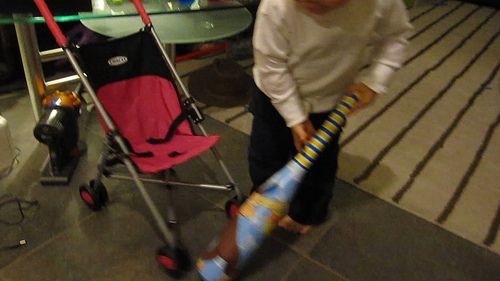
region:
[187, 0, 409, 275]
A child is holding a bat.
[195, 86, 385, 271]
The bat has cartoon characters on it.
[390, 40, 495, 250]
A striped rug.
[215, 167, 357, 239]
The child is barefoot.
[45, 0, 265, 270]
An unoccupied stroller.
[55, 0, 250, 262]
The stroller is red and black.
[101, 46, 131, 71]
The logo of the stroller manufacturer.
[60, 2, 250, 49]
A frosted glass table.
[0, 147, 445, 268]
Tile flooring.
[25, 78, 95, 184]
A handheld vacuum cleaner.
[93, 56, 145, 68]
Label on black portion of stroller.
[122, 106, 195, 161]
Safety belts on stroller.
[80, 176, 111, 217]
Back wheel on stroller.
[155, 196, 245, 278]
Front wheels of stroller.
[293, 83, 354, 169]
Stripes on bat held by child.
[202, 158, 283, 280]
Top of bat held by child standing up.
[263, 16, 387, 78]
White shirt worn by child holding the bat.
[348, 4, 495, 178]
Striped rug behind child holding the bat.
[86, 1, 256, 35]
Round table behind pink and black stroller.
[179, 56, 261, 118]
Brown hat placed on striped rug behind child holding bat.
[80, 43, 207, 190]
Stroller is red and black in color.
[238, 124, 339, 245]
The base ball bat is blue in color.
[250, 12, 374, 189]
Boy is holding the bat.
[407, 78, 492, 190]
The mat is brown in color.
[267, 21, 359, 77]
The boy is white in color.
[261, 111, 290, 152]
pant is black color.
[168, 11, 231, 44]
Table is green in color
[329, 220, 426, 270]
Floor is grey in color.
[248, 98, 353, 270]
Boy is standing in the floor.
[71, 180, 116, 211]
Wheels are in black and red color.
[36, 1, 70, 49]
Pink handle on stroller.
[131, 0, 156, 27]
Pink handle on stroller.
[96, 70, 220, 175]
Pink seat on stroller.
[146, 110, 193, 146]
Black strap on seat.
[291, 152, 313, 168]
Yellow stripe on bat.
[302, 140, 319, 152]
Blue stripe on bat.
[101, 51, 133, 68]
White logo on stroller.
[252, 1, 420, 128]
White shirt on child.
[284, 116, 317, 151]
Hand holding a bat.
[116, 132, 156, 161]
Black strap on stroller.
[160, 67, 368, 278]
Bat in boys hand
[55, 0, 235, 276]
red stroller on floor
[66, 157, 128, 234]
two red and black wheels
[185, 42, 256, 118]
hat on the floor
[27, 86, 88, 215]
Fan on the floor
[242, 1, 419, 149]
White shirt on boy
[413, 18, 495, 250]
Striped Rug on floor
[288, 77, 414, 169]
boys hands holding bat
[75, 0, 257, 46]
clear shield on chair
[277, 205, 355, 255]
Bare feet on boy